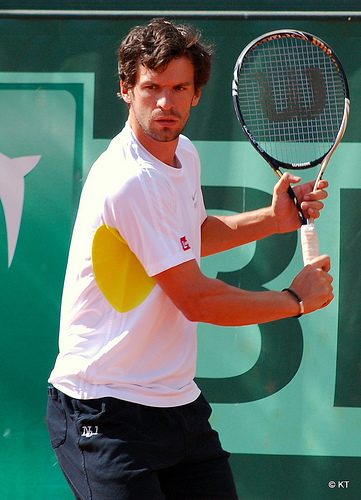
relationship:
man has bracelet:
[39, 11, 339, 499] [277, 285, 307, 324]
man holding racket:
[39, 11, 339, 499] [229, 23, 359, 285]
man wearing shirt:
[39, 11, 339, 499] [41, 123, 219, 419]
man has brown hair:
[39, 11, 339, 499] [99, 7, 223, 152]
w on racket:
[255, 57, 336, 126] [229, 23, 359, 285]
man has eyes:
[39, 11, 339, 499] [136, 78, 193, 96]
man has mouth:
[39, 11, 339, 499] [151, 115, 180, 129]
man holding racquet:
[39, 11, 339, 499] [229, 23, 359, 285]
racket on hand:
[229, 23, 359, 285] [267, 170, 331, 238]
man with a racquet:
[39, 11, 339, 499] [229, 23, 359, 285]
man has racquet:
[39, 11, 339, 499] [229, 23, 359, 285]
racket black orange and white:
[229, 23, 359, 285] [287, 27, 360, 180]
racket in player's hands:
[229, 23, 359, 285] [262, 166, 341, 318]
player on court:
[39, 11, 339, 499] [5, 3, 360, 495]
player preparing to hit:
[39, 11, 339, 499] [235, 24, 350, 180]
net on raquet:
[235, 24, 350, 180] [229, 23, 359, 285]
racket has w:
[229, 23, 359, 285] [255, 57, 336, 126]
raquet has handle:
[229, 23, 359, 285] [294, 220, 323, 270]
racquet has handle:
[229, 23, 359, 285] [296, 220, 320, 272]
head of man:
[99, 7, 223, 152] [39, 11, 339, 499]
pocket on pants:
[70, 400, 120, 440] [39, 383, 241, 498]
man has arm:
[39, 11, 339, 499] [118, 173, 338, 339]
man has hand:
[39, 11, 339, 499] [267, 170, 331, 238]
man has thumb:
[39, 11, 339, 499] [270, 169, 303, 199]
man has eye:
[39, 11, 339, 499] [137, 81, 162, 95]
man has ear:
[39, 11, 339, 499] [115, 74, 138, 106]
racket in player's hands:
[229, 23, 351, 278] [291, 260, 334, 317]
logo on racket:
[255, 57, 336, 126] [235, 50, 357, 270]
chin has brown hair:
[129, 107, 191, 147] [116, 17, 215, 89]